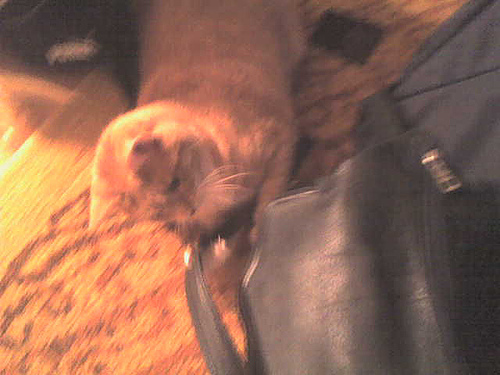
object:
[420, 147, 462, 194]
zipper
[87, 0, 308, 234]
cat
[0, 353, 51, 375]
floor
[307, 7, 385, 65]
object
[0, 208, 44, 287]
floor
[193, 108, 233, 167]
hair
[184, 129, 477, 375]
purse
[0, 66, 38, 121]
floor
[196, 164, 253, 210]
whiskers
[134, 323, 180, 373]
floor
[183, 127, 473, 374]
bag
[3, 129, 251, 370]
carpet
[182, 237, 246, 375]
strap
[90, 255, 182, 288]
floor